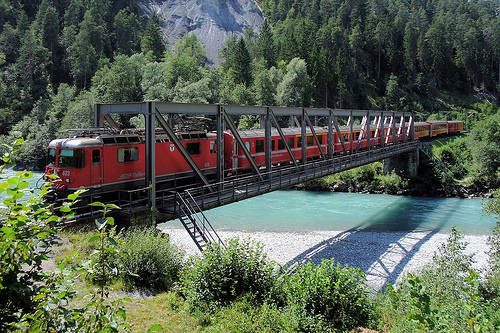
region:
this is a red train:
[38, 103, 498, 197]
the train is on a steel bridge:
[45, 81, 497, 208]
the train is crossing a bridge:
[45, 110, 491, 190]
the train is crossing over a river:
[47, 100, 485, 177]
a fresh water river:
[194, 175, 494, 228]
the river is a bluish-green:
[200, 173, 497, 233]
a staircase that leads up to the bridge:
[160, 183, 251, 283]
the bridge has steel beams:
[76, 90, 473, 207]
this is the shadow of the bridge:
[258, 179, 484, 312]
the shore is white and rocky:
[167, 223, 499, 299]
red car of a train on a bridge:
[35, 120, 227, 207]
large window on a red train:
[115, 142, 145, 165]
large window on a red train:
[182, 139, 204, 159]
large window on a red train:
[252, 137, 267, 157]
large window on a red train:
[275, 137, 289, 151]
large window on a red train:
[305, 134, 313, 147]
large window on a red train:
[58, 147, 88, 169]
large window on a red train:
[90, 146, 100, 166]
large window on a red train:
[46, 145, 58, 170]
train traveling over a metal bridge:
[0, 88, 467, 266]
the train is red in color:
[105, 160, 119, 178]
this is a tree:
[216, 247, 286, 291]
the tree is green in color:
[231, 244, 250, 273]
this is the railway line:
[239, 164, 279, 190]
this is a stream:
[319, 195, 389, 211]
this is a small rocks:
[355, 233, 407, 259]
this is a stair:
[180, 200, 214, 242]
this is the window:
[118, 146, 142, 165]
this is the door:
[89, 148, 106, 185]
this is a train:
[43, 135, 155, 189]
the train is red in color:
[87, 155, 100, 172]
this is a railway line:
[171, 187, 243, 212]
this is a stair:
[171, 195, 211, 243]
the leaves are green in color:
[243, 262, 259, 279]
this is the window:
[117, 146, 137, 160]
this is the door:
[91, 152, 105, 181]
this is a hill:
[163, 10, 232, 38]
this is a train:
[38, 98, 466, 225]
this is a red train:
[42, 100, 465, 200]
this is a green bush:
[102, 220, 167, 290]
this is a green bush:
[175, 236, 270, 326]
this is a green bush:
[275, 255, 360, 330]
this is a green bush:
[387, 225, 492, 325]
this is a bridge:
[38, 95, 413, 220]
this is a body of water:
[266, 192, 351, 227]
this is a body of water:
[402, 196, 475, 221]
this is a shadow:
[303, 230, 428, 260]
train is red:
[46, 121, 469, 191]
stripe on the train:
[237, 136, 390, 163]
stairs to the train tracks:
[174, 187, 228, 266]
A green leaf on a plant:
[43, 34, 48, 36]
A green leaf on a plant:
[43, 11, 48, 19]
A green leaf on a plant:
[323, 26, 327, 31]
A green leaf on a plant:
[378, 25, 380, 28]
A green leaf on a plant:
[409, 33, 411, 36]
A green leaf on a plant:
[453, 26, 455, 27]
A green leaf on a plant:
[354, 31, 356, 33]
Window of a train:
[117, 145, 139, 163]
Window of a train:
[183, 138, 202, 158]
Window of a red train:
[118, 146, 140, 164]